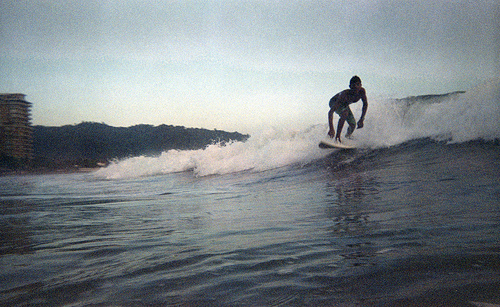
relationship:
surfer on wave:
[325, 72, 370, 146] [84, 73, 497, 190]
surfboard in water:
[315, 136, 361, 152] [4, 98, 487, 303]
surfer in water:
[325, 72, 370, 146] [4, 98, 487, 303]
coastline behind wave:
[1, 151, 102, 186] [84, 73, 497, 190]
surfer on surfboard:
[325, 72, 370, 146] [315, 136, 361, 152]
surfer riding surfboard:
[325, 72, 370, 146] [315, 136, 361, 152]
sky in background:
[2, 2, 498, 133] [2, 2, 498, 216]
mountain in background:
[25, 109, 229, 168] [2, 2, 498, 216]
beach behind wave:
[2, 165, 104, 184] [84, 73, 497, 190]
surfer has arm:
[325, 72, 370, 146] [359, 94, 371, 126]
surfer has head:
[325, 72, 370, 146] [342, 75, 367, 96]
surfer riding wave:
[325, 72, 370, 146] [84, 73, 497, 190]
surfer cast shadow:
[325, 72, 370, 146] [315, 155, 388, 271]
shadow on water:
[315, 155, 388, 271] [4, 98, 487, 303]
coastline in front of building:
[1, 151, 102, 186] [1, 80, 36, 171]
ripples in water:
[68, 234, 405, 303] [4, 98, 487, 303]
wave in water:
[84, 73, 497, 190] [4, 98, 487, 303]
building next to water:
[1, 80, 36, 171] [4, 98, 487, 303]